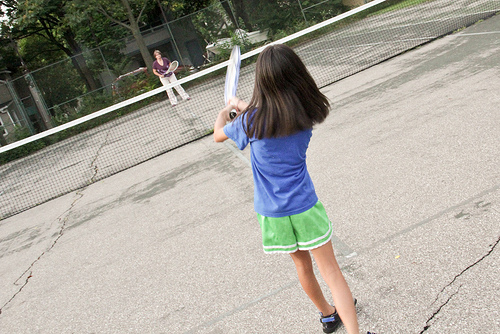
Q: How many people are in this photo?
A: Two.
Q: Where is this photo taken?
A: Tennis court.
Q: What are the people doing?
A: Playing tennis.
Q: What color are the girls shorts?
A: Green.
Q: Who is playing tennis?
A: A girl and woman.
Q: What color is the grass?
A: Green.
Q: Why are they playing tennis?
A: To have fun.